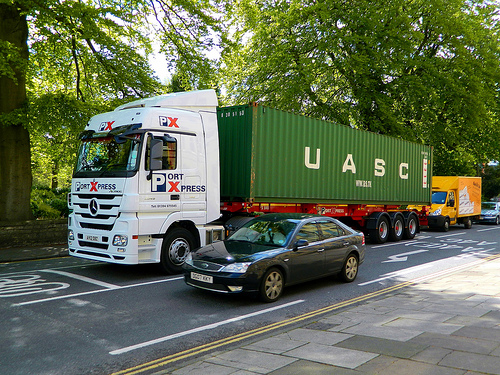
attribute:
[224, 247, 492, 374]
side walk — concrete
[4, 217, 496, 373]
line — white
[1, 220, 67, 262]
wall — low, brick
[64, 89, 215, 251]
truck — white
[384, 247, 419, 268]
arrow — white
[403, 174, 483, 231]
truck — yellow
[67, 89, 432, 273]
truck — large, big, in the picture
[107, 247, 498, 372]
lines — yellow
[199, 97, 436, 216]
container — green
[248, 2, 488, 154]
tree — leafy, green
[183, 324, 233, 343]
line — double, yellow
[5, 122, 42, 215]
tree trunk — big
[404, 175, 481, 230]
yellow truck — bright, box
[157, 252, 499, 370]
sidewalk — in the picture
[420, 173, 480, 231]
van — yellow 